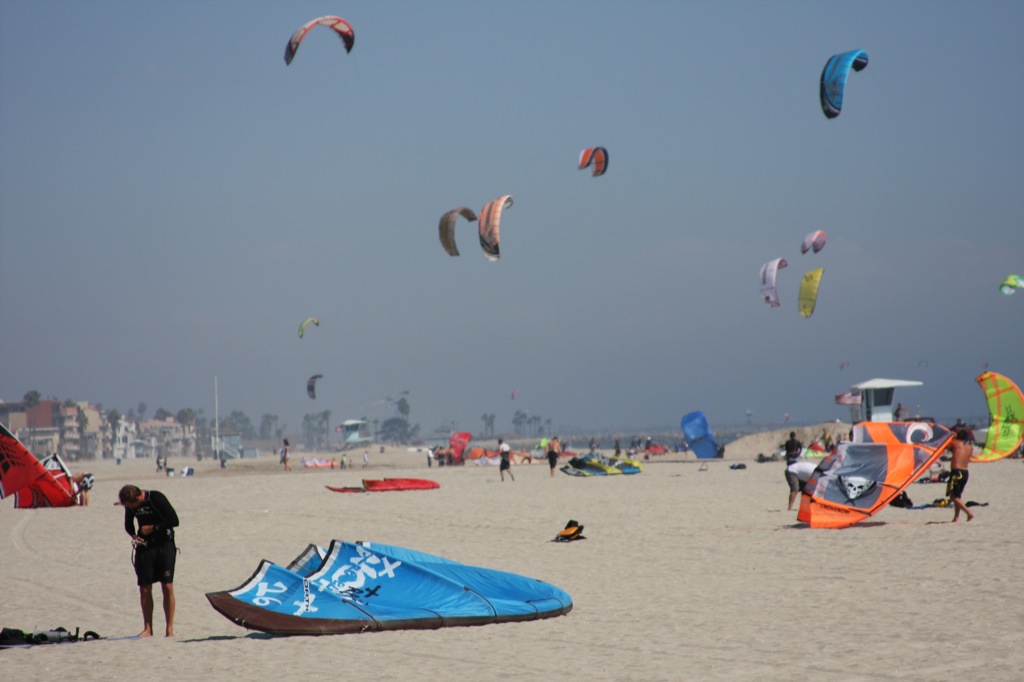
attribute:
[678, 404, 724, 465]
kite — blue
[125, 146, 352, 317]
clouds — white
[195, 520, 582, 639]
parachute — blue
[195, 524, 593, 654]
parachute — blue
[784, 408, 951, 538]
parachute — orange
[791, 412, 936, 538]
parachute — orange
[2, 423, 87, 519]
parachute — red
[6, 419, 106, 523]
parachute — red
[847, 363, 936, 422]
lifeguard — white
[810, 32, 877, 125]
kite — large, blue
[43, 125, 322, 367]
clouds — white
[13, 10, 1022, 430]
sky — blue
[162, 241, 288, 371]
clouds — white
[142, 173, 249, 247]
clouds — white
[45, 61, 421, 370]
sky — blue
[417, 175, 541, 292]
kite — flying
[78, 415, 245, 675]
man — standing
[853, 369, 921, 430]
stand — white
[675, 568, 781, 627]
sand — beige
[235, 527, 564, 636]
kite — blue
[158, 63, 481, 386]
sky — blue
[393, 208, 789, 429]
sky — blue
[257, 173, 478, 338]
clouds — white 